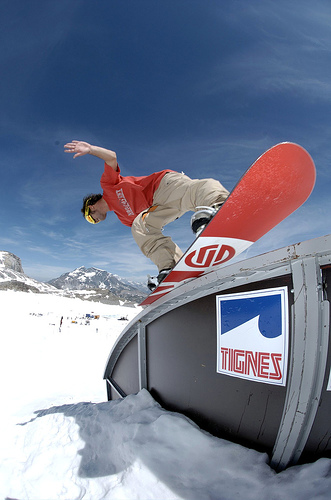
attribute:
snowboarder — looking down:
[63, 139, 232, 290]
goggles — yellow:
[85, 192, 95, 224]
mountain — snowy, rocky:
[47, 264, 154, 307]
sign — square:
[214, 287, 295, 390]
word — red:
[221, 346, 286, 380]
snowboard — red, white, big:
[137, 141, 317, 309]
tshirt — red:
[101, 163, 173, 229]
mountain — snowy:
[2, 247, 67, 297]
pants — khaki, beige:
[129, 169, 231, 274]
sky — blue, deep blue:
[1, 0, 330, 289]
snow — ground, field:
[3, 287, 329, 498]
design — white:
[145, 236, 255, 298]